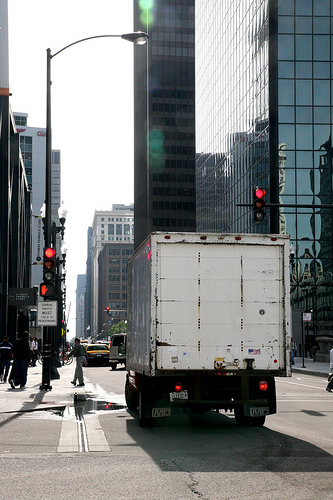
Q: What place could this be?
A: It is a street.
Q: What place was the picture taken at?
A: It was taken at the street.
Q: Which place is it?
A: It is a street.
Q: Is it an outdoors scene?
A: Yes, it is outdoors.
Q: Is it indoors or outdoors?
A: It is outdoors.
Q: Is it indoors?
A: No, it is outdoors.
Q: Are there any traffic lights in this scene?
A: Yes, there is a traffic light.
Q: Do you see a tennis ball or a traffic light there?
A: Yes, there is a traffic light.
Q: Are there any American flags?
A: No, there are no American flags.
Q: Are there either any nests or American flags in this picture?
A: No, there are no American flags or nests.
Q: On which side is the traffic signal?
A: The traffic signal is on the left of the image.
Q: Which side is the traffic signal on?
A: The traffic signal is on the left of the image.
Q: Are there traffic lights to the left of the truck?
A: Yes, there is a traffic light to the left of the truck.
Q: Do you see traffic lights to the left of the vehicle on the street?
A: Yes, there is a traffic light to the left of the truck.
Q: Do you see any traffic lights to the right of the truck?
A: No, the traffic light is to the left of the truck.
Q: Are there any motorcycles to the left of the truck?
A: No, there is a traffic light to the left of the truck.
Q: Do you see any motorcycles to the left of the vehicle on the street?
A: No, there is a traffic light to the left of the truck.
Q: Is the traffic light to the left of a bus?
A: No, the traffic light is to the left of the truck.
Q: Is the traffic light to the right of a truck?
A: No, the traffic light is to the left of a truck.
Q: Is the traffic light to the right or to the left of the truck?
A: The traffic light is to the left of the truck.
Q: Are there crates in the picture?
A: No, there are no crates.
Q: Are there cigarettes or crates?
A: No, there are no crates or cigarettes.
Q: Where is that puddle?
A: The puddle is on the street.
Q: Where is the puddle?
A: The puddle is on the street.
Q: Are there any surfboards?
A: No, there are no surfboards.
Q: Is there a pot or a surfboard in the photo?
A: No, there are no surfboards or pots.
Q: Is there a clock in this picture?
A: No, there are no clocks.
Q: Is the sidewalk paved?
A: Yes, the sidewalk is paved.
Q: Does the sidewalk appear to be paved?
A: Yes, the sidewalk is paved.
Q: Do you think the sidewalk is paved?
A: Yes, the sidewalk is paved.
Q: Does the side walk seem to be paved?
A: Yes, the side walk is paved.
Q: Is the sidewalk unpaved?
A: No, the sidewalk is paved.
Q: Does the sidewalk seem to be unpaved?
A: No, the sidewalk is paved.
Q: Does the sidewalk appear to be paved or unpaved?
A: The sidewalk is paved.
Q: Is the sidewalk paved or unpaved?
A: The sidewalk is paved.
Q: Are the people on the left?
A: Yes, the people are on the left of the image.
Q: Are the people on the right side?
A: No, the people are on the left of the image.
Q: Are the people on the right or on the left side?
A: The people are on the left of the image.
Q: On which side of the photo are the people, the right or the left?
A: The people are on the left of the image.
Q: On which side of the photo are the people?
A: The people are on the left of the image.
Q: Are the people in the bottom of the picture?
A: Yes, the people are in the bottom of the image.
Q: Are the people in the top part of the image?
A: No, the people are in the bottom of the image.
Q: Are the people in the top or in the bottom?
A: The people are in the bottom of the image.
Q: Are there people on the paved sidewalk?
A: Yes, there are people on the side walk.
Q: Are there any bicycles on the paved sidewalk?
A: No, there are people on the sidewalk.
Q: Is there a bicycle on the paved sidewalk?
A: No, there are people on the sidewalk.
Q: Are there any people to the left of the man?
A: Yes, there are people to the left of the man.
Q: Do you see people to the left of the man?
A: Yes, there are people to the left of the man.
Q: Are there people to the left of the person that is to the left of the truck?
A: Yes, there are people to the left of the man.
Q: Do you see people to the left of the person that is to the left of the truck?
A: Yes, there are people to the left of the man.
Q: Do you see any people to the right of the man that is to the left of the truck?
A: No, the people are to the left of the man.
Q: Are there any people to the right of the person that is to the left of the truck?
A: No, the people are to the left of the man.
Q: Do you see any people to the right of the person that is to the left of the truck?
A: No, the people are to the left of the man.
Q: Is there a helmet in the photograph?
A: No, there are no helmets.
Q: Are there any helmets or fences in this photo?
A: No, there are no helmets or fences.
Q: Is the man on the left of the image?
A: Yes, the man is on the left of the image.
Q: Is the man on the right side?
A: No, the man is on the left of the image.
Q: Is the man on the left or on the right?
A: The man is on the left of the image.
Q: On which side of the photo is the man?
A: The man is on the left of the image.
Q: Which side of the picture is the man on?
A: The man is on the left of the image.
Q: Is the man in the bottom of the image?
A: Yes, the man is in the bottom of the image.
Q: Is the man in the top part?
A: No, the man is in the bottom of the image.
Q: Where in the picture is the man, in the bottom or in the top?
A: The man is in the bottom of the image.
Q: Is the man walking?
A: Yes, the man is walking.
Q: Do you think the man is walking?
A: Yes, the man is walking.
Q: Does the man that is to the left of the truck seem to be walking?
A: Yes, the man is walking.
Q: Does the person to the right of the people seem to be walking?
A: Yes, the man is walking.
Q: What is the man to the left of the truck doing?
A: The man is walking.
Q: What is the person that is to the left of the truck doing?
A: The man is walking.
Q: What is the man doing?
A: The man is walking.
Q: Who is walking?
A: The man is walking.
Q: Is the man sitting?
A: No, the man is walking.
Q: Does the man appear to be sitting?
A: No, the man is walking.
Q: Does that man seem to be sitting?
A: No, the man is walking.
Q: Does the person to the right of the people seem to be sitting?
A: No, the man is walking.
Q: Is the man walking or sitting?
A: The man is walking.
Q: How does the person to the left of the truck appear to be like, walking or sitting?
A: The man is walking.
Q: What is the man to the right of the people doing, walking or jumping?
A: The man is walking.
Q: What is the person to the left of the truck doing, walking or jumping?
A: The man is walking.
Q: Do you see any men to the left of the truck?
A: Yes, there is a man to the left of the truck.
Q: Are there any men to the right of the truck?
A: No, the man is to the left of the truck.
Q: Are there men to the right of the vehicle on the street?
A: No, the man is to the left of the truck.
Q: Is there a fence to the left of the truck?
A: No, there is a man to the left of the truck.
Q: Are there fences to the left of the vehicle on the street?
A: No, there is a man to the left of the truck.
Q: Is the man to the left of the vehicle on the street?
A: Yes, the man is to the left of the truck.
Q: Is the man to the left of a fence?
A: No, the man is to the left of the truck.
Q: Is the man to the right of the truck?
A: No, the man is to the left of the truck.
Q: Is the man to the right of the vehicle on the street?
A: No, the man is to the left of the truck.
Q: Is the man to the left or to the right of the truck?
A: The man is to the left of the truck.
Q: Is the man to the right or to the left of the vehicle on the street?
A: The man is to the left of the truck.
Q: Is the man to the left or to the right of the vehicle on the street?
A: The man is to the left of the truck.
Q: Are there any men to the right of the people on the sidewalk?
A: Yes, there is a man to the right of the people.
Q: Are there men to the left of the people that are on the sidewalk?
A: No, the man is to the right of the people.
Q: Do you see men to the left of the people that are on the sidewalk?
A: No, the man is to the right of the people.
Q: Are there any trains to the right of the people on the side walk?
A: No, there is a man to the right of the people.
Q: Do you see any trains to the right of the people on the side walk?
A: No, there is a man to the right of the people.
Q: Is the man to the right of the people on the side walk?
A: Yes, the man is to the right of the people.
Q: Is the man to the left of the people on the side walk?
A: No, the man is to the right of the people.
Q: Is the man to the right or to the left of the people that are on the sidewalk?
A: The man is to the right of the people.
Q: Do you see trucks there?
A: Yes, there is a truck.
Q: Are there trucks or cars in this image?
A: Yes, there is a truck.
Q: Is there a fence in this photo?
A: No, there are no fences.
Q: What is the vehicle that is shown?
A: The vehicle is a truck.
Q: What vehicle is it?
A: The vehicle is a truck.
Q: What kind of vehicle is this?
A: This is a truck.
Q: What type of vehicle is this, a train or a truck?
A: This is a truck.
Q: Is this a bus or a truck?
A: This is a truck.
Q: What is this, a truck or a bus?
A: This is a truck.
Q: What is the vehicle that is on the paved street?
A: The vehicle is a truck.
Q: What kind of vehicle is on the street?
A: The vehicle is a truck.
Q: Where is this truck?
A: The truck is on the street.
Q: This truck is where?
A: The truck is on the street.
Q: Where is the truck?
A: The truck is on the street.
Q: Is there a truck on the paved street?
A: Yes, there is a truck on the street.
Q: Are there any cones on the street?
A: No, there is a truck on the street.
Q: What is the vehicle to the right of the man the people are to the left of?
A: The vehicle is a truck.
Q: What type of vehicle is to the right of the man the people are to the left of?
A: The vehicle is a truck.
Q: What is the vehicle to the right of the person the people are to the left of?
A: The vehicle is a truck.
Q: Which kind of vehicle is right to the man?
A: The vehicle is a truck.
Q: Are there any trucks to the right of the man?
A: Yes, there is a truck to the right of the man.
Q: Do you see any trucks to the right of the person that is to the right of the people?
A: Yes, there is a truck to the right of the man.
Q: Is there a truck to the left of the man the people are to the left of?
A: No, the truck is to the right of the man.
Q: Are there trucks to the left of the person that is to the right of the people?
A: No, the truck is to the right of the man.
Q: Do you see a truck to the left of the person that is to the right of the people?
A: No, the truck is to the right of the man.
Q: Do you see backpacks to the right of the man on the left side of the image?
A: No, there is a truck to the right of the man.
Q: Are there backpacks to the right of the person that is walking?
A: No, there is a truck to the right of the man.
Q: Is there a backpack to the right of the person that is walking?
A: No, there is a truck to the right of the man.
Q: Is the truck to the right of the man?
A: Yes, the truck is to the right of the man.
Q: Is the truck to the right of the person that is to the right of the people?
A: Yes, the truck is to the right of the man.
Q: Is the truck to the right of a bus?
A: No, the truck is to the right of the man.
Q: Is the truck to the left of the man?
A: No, the truck is to the right of the man.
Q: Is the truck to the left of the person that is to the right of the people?
A: No, the truck is to the right of the man.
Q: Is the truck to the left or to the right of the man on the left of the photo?
A: The truck is to the right of the man.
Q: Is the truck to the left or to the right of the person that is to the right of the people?
A: The truck is to the right of the man.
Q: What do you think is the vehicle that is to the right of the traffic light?
A: The vehicle is a truck.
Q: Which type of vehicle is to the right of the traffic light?
A: The vehicle is a truck.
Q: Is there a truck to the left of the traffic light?
A: No, the truck is to the right of the traffic light.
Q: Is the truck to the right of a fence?
A: No, the truck is to the right of a traffic light.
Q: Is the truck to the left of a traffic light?
A: No, the truck is to the right of a traffic light.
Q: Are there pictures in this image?
A: No, there are no pictures.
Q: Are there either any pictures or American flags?
A: No, there are no pictures or American flags.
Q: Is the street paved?
A: Yes, the street is paved.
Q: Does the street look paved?
A: Yes, the street is paved.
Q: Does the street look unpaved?
A: No, the street is paved.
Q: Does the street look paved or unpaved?
A: The street is paved.